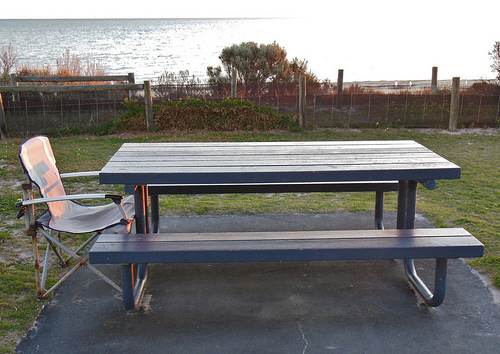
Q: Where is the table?
A: On top of the ground.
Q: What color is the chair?
A: White.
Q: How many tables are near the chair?
A: 1.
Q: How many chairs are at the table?
A: 1.